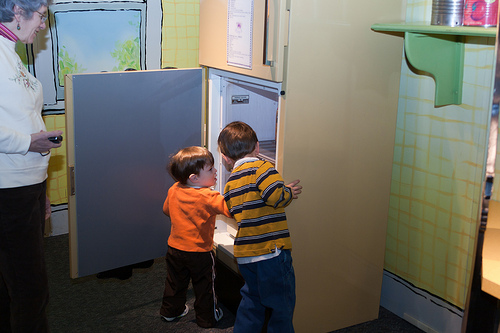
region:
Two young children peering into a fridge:
[140, 98, 316, 331]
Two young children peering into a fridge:
[148, 116, 316, 331]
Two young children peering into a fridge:
[156, 111, 314, 329]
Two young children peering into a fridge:
[152, 113, 307, 331]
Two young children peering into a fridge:
[150, 108, 310, 332]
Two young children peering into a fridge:
[152, 103, 315, 332]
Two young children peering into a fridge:
[154, 116, 316, 331]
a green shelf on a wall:
[369, 19, 496, 112]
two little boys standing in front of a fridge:
[153, 117, 303, 329]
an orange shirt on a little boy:
[161, 178, 231, 250]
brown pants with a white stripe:
[159, 245, 224, 323]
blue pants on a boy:
[232, 250, 299, 331]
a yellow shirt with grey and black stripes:
[223, 158, 295, 251]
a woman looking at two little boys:
[0, 0, 59, 332]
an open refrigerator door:
[64, 62, 206, 275]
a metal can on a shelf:
[429, 0, 464, 28]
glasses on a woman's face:
[33, 6, 53, 23]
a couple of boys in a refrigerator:
[148, 117, 306, 325]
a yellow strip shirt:
[222, 156, 297, 270]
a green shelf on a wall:
[372, 23, 496, 107]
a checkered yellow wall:
[380, 96, 487, 286]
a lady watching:
[1, 0, 51, 330]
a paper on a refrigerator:
[225, 3, 255, 71]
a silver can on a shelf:
[427, 0, 461, 28]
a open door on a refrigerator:
[64, 77, 286, 282]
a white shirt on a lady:
[2, 33, 44, 181]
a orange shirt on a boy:
[165, 187, 226, 247]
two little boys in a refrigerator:
[161, 117, 303, 331]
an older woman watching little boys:
[2, 0, 63, 331]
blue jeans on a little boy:
[230, 250, 299, 332]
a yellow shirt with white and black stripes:
[222, 156, 292, 257]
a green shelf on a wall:
[369, 18, 499, 105]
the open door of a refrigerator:
[62, 62, 205, 284]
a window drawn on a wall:
[35, 1, 158, 110]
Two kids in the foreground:
[148, 105, 321, 328]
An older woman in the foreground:
[0, 2, 83, 322]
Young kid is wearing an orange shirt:
[153, 176, 236, 264]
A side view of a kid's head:
[158, 141, 222, 196]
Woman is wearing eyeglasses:
[2, 2, 62, 56]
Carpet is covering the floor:
[41, 221, 423, 331]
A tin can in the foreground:
[425, 1, 470, 35]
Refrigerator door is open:
[52, 60, 308, 328]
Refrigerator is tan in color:
[53, 2, 415, 329]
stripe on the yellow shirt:
[223, 165, 258, 181]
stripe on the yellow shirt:
[221, 177, 256, 200]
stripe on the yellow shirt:
[222, 195, 262, 215]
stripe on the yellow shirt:
[240, 212, 286, 229]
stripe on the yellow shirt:
[231, 225, 291, 252]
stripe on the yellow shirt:
[253, 165, 278, 190]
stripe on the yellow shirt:
[220, 182, 260, 199]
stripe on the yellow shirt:
[228, 196, 264, 217]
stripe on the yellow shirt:
[237, 210, 282, 229]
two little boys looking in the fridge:
[160, 118, 300, 330]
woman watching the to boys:
[1, 0, 64, 328]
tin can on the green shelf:
[430, 5, 461, 25]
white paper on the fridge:
[222, 3, 254, 70]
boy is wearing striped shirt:
[213, 115, 305, 263]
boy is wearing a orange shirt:
[155, 138, 227, 325]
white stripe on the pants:
[200, 250, 217, 314]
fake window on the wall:
[55, 5, 160, 71]